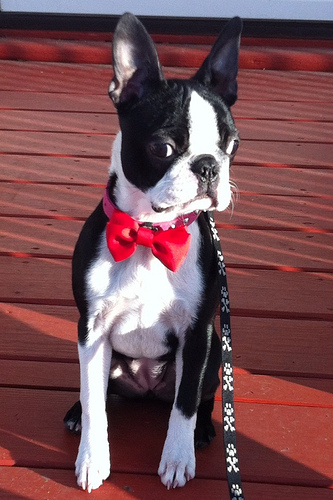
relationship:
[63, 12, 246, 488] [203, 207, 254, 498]
dog wearing leash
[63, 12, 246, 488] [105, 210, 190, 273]
dog wearing tie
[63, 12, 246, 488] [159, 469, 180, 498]
dog with nails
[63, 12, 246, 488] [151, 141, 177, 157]
dog with eye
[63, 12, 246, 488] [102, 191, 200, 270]
dog with bow-tie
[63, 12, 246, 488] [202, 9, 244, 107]
dog with ear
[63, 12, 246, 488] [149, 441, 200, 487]
dog with left paw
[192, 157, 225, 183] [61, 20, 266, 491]
nose on dog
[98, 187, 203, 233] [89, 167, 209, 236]
collar around neck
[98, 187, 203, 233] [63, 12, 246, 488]
collar around dog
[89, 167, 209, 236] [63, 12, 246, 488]
neck of dog